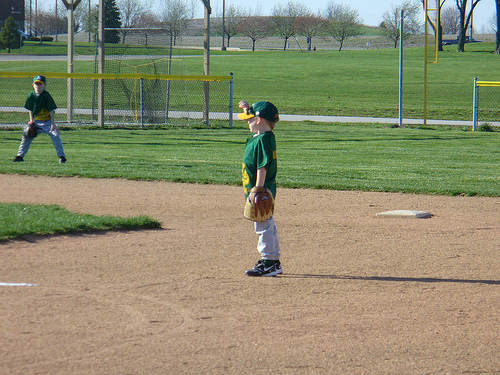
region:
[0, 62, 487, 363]
Young children playing baseball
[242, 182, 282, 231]
A glove on the child's hand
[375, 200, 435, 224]
A square white basein the dirt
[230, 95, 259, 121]
The child shields his eyes from the sun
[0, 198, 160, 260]
A thick patch of grass near the child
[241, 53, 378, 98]
The grass is cut very short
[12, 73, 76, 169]
A young child in an athletic stance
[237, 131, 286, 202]
The boy's jersey is green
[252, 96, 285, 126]
The boy wears a green baseball cap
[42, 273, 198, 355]
Small tire tracks in the dirt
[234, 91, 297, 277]
little boy standing of field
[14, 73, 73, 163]
boy standing in the outfield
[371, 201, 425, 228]
white base on baseball field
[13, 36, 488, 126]
fence along baseball field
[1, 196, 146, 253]
infield grass on baseball field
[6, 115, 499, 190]
outfield grass on baseball field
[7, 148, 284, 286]
cleats of boys playing baseball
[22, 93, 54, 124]
green shirt of child in outfield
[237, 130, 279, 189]
green shirt of child in infield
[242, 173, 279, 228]
glove of child in infield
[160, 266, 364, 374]
the ground is brown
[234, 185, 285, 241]
the glove is brown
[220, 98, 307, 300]
the child is playing baseball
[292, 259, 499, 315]
the shadow is on the ground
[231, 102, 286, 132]
the cape is green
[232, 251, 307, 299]
the shoes are black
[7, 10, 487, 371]
they are outddors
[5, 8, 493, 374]
they are in a park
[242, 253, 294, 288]
the shoe has nike symbol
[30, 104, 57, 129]
the drawing is yellow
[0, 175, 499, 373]
sandy clay under base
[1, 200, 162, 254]
green grass in front of boy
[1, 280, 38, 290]
white line on clay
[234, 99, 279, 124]
boy wearing a green cap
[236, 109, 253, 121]
yellow bill on cap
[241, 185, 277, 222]
brown leather baseball glove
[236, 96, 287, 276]
boy standing on baseball field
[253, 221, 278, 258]
boy wearing white pants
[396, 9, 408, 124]
gray metal pole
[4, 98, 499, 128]
sidewalk behind field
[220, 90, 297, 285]
A boy playing baseball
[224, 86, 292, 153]
A boy wearing a green hat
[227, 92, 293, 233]
A boy wearing a baseball glove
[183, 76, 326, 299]
A boy on a baseball field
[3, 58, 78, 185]
A boy playing baseball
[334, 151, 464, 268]
A baseball base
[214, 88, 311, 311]
A boy standing in the dirt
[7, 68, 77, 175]
A boy standing on the grass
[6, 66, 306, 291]
Two boys playing baseball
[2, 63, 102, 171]
A boy standing in front of a net